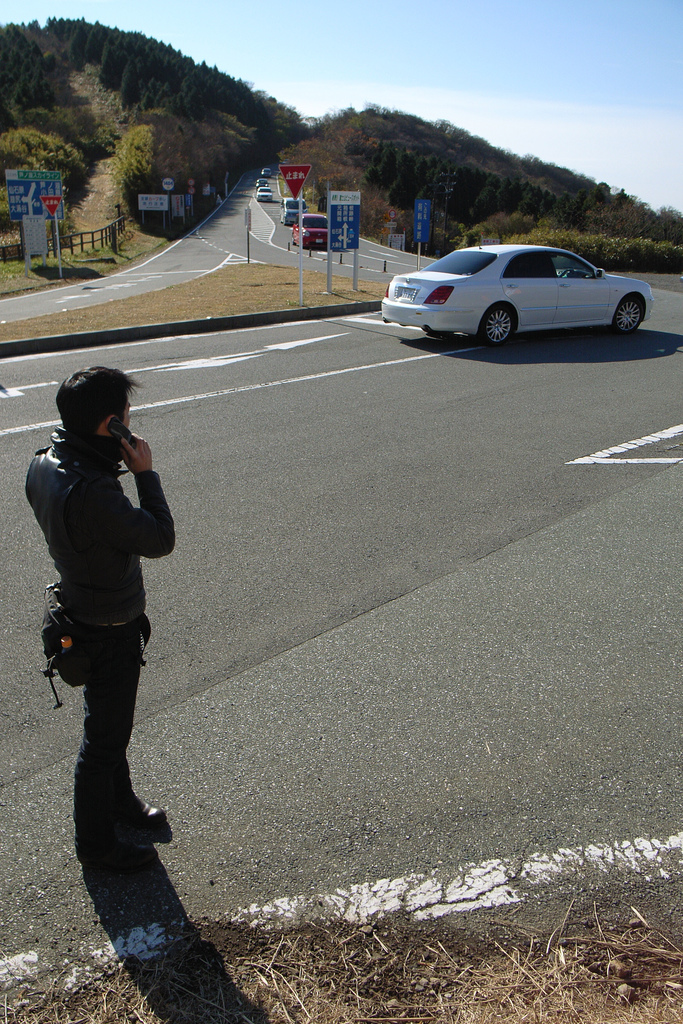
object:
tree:
[107, 123, 155, 225]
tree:
[153, 120, 186, 230]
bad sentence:
[136, 728, 215, 764]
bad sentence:
[146, 666, 196, 709]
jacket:
[26, 425, 177, 627]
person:
[24, 365, 176, 868]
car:
[381, 244, 655, 346]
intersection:
[0, 258, 682, 1024]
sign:
[414, 200, 431, 243]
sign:
[330, 191, 362, 249]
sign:
[278, 164, 312, 200]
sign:
[39, 195, 62, 215]